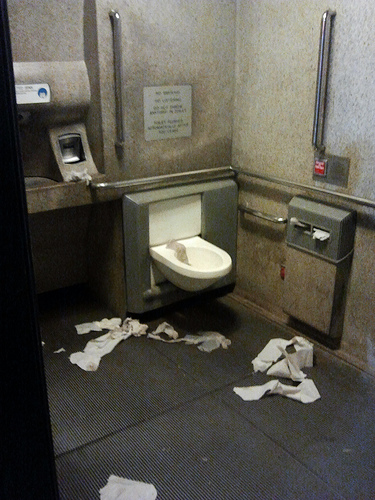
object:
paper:
[94, 472, 160, 499]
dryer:
[12, 60, 93, 121]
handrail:
[237, 203, 288, 225]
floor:
[41, 312, 361, 497]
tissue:
[11, 60, 92, 132]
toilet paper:
[57, 310, 323, 407]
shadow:
[168, 305, 238, 334]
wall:
[255, 73, 316, 144]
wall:
[192, 27, 286, 88]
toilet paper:
[286, 213, 341, 245]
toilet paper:
[71, 164, 94, 189]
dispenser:
[283, 195, 356, 265]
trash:
[233, 377, 320, 403]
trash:
[251, 333, 313, 381]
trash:
[68, 315, 146, 370]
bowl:
[174, 246, 224, 274]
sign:
[315, 161, 325, 174]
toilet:
[125, 174, 277, 317]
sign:
[143, 83, 192, 140]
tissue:
[169, 238, 188, 262]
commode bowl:
[149, 236, 233, 293]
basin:
[23, 176, 59, 188]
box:
[285, 195, 357, 264]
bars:
[103, 5, 336, 176]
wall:
[10, 3, 234, 300]